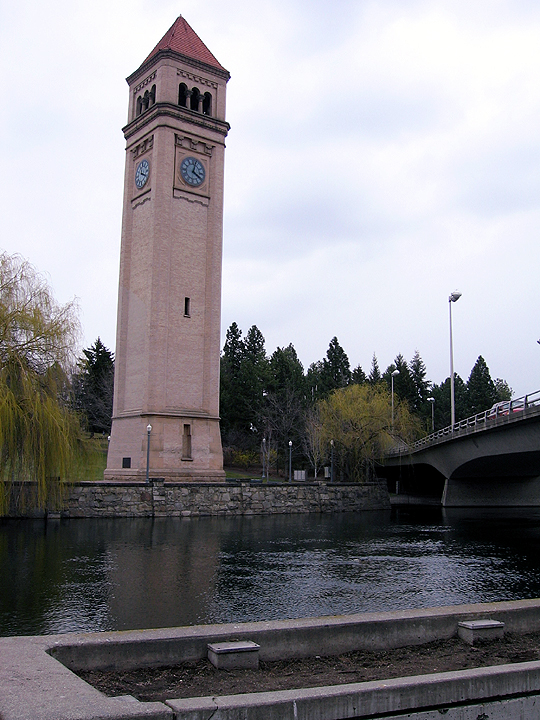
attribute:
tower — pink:
[125, 61, 242, 476]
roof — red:
[140, 18, 229, 73]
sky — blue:
[5, 6, 535, 398]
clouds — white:
[5, 6, 539, 406]